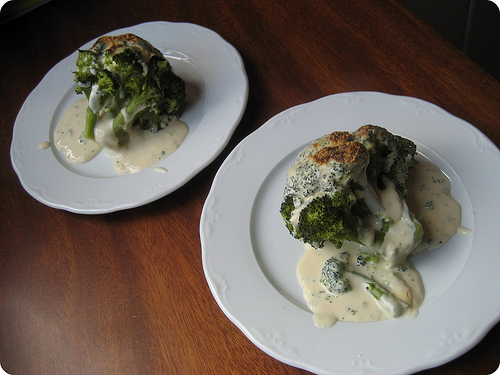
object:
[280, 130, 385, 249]
broccoli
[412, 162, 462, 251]
cream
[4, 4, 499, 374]
tabletop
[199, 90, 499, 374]
plate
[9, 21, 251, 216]
plate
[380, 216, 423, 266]
stem